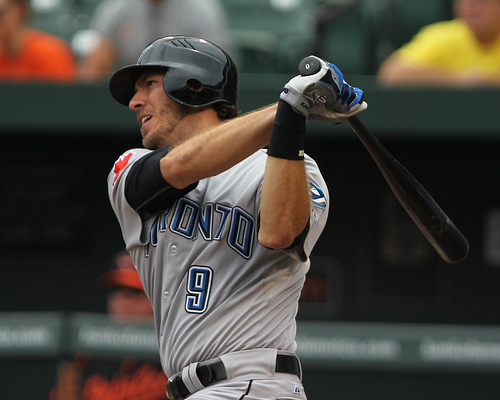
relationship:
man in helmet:
[100, 73, 319, 334] [138, 29, 217, 93]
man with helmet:
[100, 73, 319, 334] [138, 29, 217, 93]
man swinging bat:
[100, 73, 319, 334] [381, 147, 473, 277]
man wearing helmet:
[100, 73, 319, 334] [138, 29, 217, 93]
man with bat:
[100, 73, 319, 334] [381, 147, 473, 277]